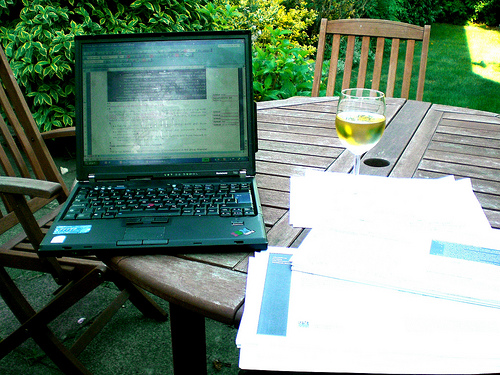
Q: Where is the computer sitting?
A: On a table.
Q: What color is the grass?
A: Green.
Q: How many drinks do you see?
A: 1.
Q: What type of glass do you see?
A: Wine glass.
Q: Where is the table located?
A: In a yard.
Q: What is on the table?
A: Computer, drink, papers.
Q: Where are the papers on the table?
A: In front of the glass.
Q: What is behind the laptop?
A: Bushes.